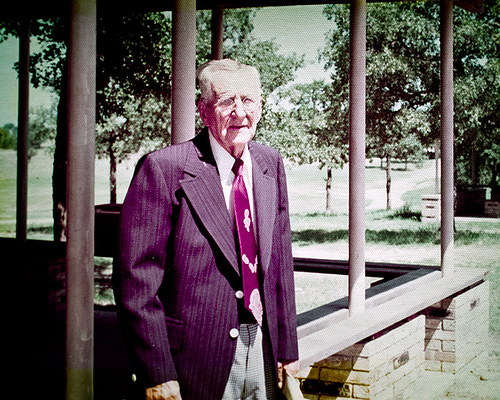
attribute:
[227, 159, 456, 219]
tie — burgundy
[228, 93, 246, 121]
nose — white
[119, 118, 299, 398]
jacket — purple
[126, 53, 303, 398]
man — old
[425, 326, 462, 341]
brick — white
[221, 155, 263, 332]
tie — purple, white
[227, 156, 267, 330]
tie — burgundy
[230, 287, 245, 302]
button — top, white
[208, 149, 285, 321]
tie — burgundy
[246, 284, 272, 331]
cone — white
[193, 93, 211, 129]
ear — old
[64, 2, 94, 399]
column — support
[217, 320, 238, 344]
button — white, plastic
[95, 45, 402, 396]
man — old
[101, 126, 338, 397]
jacket — purple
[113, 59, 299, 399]
man — old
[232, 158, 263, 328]
tie — burgundy